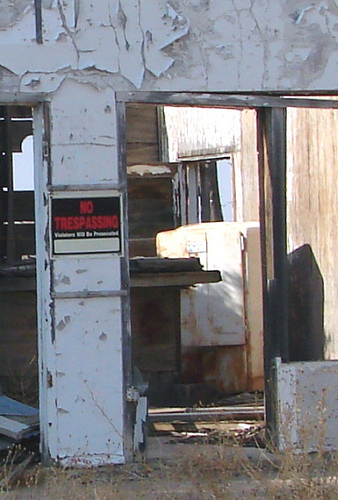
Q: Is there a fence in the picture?
A: No, there are no fences.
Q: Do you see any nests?
A: No, there are no nests.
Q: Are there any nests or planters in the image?
A: No, there are no nests or planters.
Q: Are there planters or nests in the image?
A: No, there are no nests or planters.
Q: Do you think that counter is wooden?
A: Yes, the counter is wooden.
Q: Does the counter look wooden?
A: Yes, the counter is wooden.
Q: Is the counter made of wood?
A: Yes, the counter is made of wood.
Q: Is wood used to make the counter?
A: Yes, the counter is made of wood.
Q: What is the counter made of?
A: The counter is made of wood.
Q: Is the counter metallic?
A: No, the counter is wooden.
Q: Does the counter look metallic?
A: No, the counter is wooden.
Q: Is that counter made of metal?
A: No, the counter is made of wood.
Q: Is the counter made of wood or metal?
A: The counter is made of wood.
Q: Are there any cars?
A: No, there are no cars.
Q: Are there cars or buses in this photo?
A: No, there are no cars or buses.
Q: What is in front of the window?
A: The building is in front of the window.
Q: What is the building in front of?
A: The building is in front of the window.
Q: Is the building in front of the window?
A: Yes, the building is in front of the window.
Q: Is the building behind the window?
A: No, the building is in front of the window.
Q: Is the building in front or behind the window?
A: The building is in front of the window.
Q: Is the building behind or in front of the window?
A: The building is in front of the window.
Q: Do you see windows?
A: Yes, there is a window.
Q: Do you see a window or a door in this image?
A: Yes, there is a window.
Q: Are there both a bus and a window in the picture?
A: No, there is a window but no buses.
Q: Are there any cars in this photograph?
A: No, there are no cars.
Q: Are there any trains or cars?
A: No, there are no cars or trains.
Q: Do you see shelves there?
A: No, there are no shelves.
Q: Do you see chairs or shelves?
A: No, there are no shelves or chairs.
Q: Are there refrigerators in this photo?
A: Yes, there is a refrigerator.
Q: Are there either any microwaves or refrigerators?
A: Yes, there is a refrigerator.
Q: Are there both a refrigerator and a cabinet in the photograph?
A: No, there is a refrigerator but no cabinets.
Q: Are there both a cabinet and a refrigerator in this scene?
A: No, there is a refrigerator but no cabinets.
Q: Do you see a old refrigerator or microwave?
A: Yes, there is an old refrigerator.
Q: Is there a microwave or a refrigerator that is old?
A: Yes, the refrigerator is old.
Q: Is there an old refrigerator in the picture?
A: Yes, there is an old refrigerator.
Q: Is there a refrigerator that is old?
A: Yes, there is a refrigerator that is old.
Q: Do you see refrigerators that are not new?
A: Yes, there is a old refrigerator.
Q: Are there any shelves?
A: No, there are no shelves.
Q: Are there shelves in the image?
A: No, there are no shelves.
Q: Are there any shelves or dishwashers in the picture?
A: No, there are no shelves or dishwashers.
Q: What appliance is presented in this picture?
A: The appliance is a refrigerator.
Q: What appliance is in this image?
A: The appliance is a refrigerator.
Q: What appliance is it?
A: The appliance is a refrigerator.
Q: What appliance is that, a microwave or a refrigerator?
A: That is a refrigerator.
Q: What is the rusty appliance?
A: The appliance is a refrigerator.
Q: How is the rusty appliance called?
A: The appliance is a refrigerator.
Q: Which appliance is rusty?
A: The appliance is a refrigerator.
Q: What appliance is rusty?
A: The appliance is a refrigerator.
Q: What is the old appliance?
A: The appliance is a refrigerator.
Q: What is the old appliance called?
A: The appliance is a refrigerator.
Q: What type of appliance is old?
A: The appliance is a refrigerator.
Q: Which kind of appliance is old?
A: The appliance is a refrigerator.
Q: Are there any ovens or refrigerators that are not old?
A: No, there is a refrigerator but it is old.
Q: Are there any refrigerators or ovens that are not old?
A: No, there is a refrigerator but it is old.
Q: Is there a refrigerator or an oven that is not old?
A: No, there is a refrigerator but it is old.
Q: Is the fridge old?
A: Yes, the fridge is old.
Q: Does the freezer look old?
A: Yes, the freezer is old.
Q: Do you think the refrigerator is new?
A: No, the refrigerator is old.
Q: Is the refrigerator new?
A: No, the refrigerator is old.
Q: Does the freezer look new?
A: No, the freezer is old.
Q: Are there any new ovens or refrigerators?
A: No, there is a refrigerator but it is old.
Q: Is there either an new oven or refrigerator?
A: No, there is a refrigerator but it is old.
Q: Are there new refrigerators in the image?
A: No, there is a refrigerator but it is old.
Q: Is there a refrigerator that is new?
A: No, there is a refrigerator but it is old.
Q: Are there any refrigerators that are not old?
A: No, there is a refrigerator but it is old.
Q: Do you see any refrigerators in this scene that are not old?
A: No, there is a refrigerator but it is old.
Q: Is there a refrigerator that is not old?
A: No, there is a refrigerator but it is old.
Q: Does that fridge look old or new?
A: The fridge is old.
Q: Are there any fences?
A: No, there are no fences.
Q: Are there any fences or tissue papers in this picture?
A: No, there are no fences or tissue papers.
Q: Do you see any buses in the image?
A: No, there are no buses.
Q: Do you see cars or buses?
A: No, there are no buses or cars.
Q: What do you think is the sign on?
A: The sign is on the wall.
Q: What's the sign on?
A: The sign is on the wall.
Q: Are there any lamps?
A: No, there are no lamps.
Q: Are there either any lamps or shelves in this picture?
A: No, there are no lamps or shelves.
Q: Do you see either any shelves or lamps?
A: No, there are no lamps or shelves.